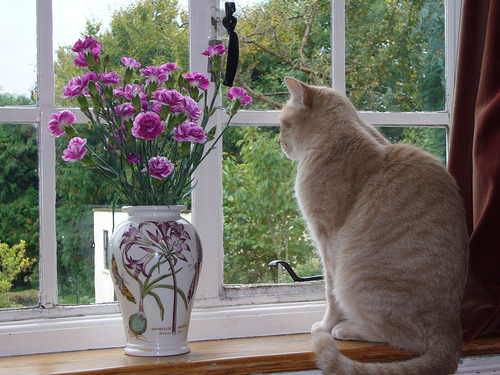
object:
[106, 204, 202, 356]
flowers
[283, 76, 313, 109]
ear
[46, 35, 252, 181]
flowers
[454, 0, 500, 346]
curtain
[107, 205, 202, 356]
vase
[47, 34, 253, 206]
stems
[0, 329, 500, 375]
windowsill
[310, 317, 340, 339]
front foot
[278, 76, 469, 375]
cat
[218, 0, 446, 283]
tree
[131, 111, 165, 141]
flower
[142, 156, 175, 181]
purple flower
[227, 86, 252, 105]
purple flower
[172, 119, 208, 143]
purple flower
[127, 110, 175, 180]
purple flower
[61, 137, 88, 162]
purple flower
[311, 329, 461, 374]
tail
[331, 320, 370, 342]
foot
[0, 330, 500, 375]
sill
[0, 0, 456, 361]
window